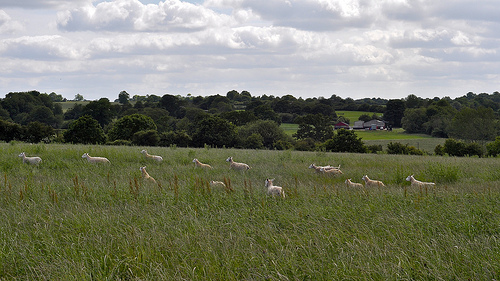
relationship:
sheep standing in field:
[261, 174, 286, 197] [0, 139, 484, 279]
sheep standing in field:
[343, 176, 363, 190] [0, 139, 484, 279]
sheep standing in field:
[360, 171, 385, 188] [0, 139, 484, 279]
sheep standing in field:
[136, 163, 158, 184] [0, 139, 484, 279]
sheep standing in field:
[80, 150, 111, 166] [0, 139, 484, 279]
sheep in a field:
[15, 142, 444, 201] [0, 139, 484, 279]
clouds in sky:
[64, 8, 264, 63] [51, 9, 302, 74]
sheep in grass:
[19, 155, 435, 205] [18, 148, 438, 195]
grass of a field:
[205, 210, 311, 252] [33, 163, 427, 273]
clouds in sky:
[59, 6, 221, 36] [23, 11, 442, 132]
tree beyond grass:
[67, 99, 120, 144] [45, 131, 165, 176]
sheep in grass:
[339, 174, 368, 194] [295, 182, 375, 220]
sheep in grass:
[313, 156, 337, 175] [295, 182, 375, 220]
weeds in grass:
[119, 174, 146, 204] [53, 186, 273, 276]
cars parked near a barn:
[368, 122, 393, 131] [352, 115, 402, 134]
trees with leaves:
[393, 84, 495, 160] [442, 100, 477, 130]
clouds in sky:
[3, 6, 497, 68] [0, 0, 498, 108]